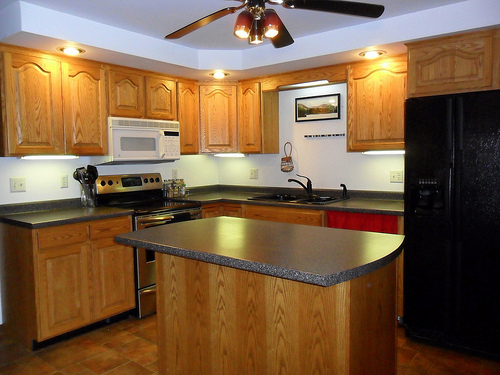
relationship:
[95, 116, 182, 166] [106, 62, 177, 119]
microwave under cabinet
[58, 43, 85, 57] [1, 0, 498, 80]
lamps in ceiling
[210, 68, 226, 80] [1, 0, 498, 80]
round light in ceiling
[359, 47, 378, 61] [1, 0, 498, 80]
round light in ceiling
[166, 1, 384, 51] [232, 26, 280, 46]
ceiling fan with lights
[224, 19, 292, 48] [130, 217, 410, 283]
light reflected on counter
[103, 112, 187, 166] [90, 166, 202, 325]
microwave above stove